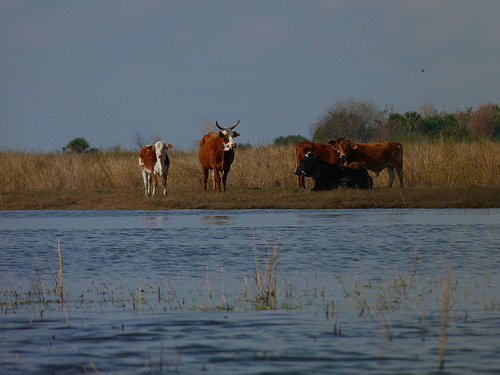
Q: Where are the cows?
A: By the water.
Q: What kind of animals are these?
A: Cows.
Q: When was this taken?
A: Daytime.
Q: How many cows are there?
A: 5.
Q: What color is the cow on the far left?
A: Brown and white.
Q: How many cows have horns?
A: 1.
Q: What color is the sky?
A: Blue.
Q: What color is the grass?
A: Brown.